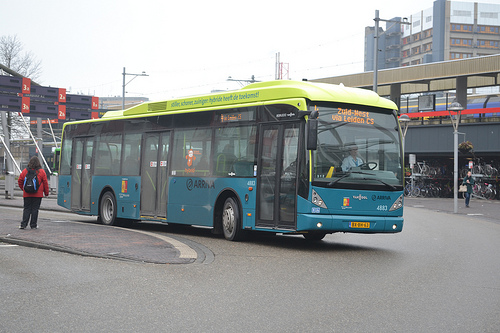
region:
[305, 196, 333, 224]
a right headlight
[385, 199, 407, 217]
a left headlight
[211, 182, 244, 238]
right front tire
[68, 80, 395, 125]
neon green bus top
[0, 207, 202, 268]
roadside curb near street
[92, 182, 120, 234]
rear white wheel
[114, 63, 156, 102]
street light on pole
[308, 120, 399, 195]
windshield on a bus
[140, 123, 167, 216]
side loading doors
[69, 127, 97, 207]
rear loading doors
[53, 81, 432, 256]
A large transit bus.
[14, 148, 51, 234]
A woman with dark hair.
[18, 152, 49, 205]
A dark back pack with blue stripes.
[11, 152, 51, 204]
A woman wearing a red coat.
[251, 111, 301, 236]
The front doors on a bus.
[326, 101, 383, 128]
Yellow writing on front of bus.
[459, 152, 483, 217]
A person walking down sidewalk.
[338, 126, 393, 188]
The driver of the bus.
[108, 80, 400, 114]
The top of the bus is yellow.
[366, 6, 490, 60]
A building in the background.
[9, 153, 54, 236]
Woman in red standing with blue and black backpack on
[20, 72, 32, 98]
small red 3a sign up high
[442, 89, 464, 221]
Tall skinny pole with light on it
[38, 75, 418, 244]
Blue bus with lime green top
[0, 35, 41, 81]
Top of a tree in background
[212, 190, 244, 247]
Wheel of the bus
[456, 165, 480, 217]
Woman walking with very large purse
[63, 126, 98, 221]
Back double doors of a bus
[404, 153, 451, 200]
lots of bicycles on display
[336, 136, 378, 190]
person driving the bus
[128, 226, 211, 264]
semi circular broad white pattern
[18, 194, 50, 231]
large black pants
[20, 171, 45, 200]
black and light blue backpack with writing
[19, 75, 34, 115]
large red and white banners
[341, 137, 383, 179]
bus driver in blue jacket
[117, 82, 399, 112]
top of bus in lime green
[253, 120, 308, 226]
large clear door with wide black borders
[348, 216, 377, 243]
yellow license plate with large letters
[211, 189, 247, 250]
large black wheel with silver trim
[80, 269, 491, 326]
solid street area painted tan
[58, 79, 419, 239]
A yellow and blue bus.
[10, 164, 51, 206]
A woman wearing a backpack.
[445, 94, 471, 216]
A lamp post on sidewalk.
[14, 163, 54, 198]
A woman wearing a red jacket.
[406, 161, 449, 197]
Bicycles on a rack.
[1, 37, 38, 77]
A tree with no leaves.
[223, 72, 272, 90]
The top of a crane.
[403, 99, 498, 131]
A red stripe along the side of a building.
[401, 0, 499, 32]
Top of building is white.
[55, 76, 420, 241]
A bus turning the corner.